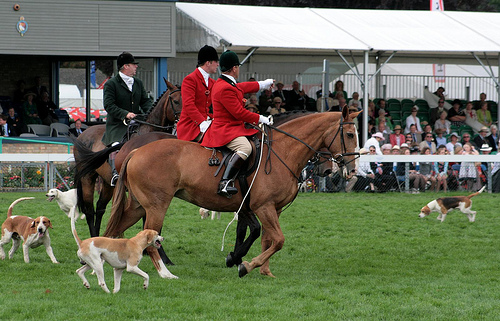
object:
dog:
[416, 186, 486, 223]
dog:
[0, 196, 59, 264]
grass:
[2, 190, 496, 319]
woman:
[474, 99, 492, 129]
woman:
[433, 110, 450, 134]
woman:
[388, 125, 406, 147]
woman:
[446, 130, 459, 152]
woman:
[330, 78, 347, 103]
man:
[102, 51, 149, 186]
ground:
[302, 199, 452, 225]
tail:
[69, 129, 127, 183]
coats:
[199, 75, 258, 148]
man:
[199, 48, 276, 196]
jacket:
[100, 72, 150, 144]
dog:
[43, 186, 87, 223]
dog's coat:
[63, 192, 75, 207]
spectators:
[0, 78, 498, 190]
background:
[0, 0, 497, 158]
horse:
[100, 111, 331, 266]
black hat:
[218, 48, 242, 71]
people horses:
[74, 77, 363, 278]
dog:
[74, 228, 164, 295]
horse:
[74, 76, 181, 265]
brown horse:
[98, 103, 363, 277]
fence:
[0, 153, 500, 188]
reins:
[262, 111, 361, 183]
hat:
[219, 50, 243, 71]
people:
[257, 80, 497, 189]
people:
[101, 45, 279, 198]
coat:
[100, 76, 153, 147]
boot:
[216, 151, 247, 195]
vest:
[477, 104, 491, 123]